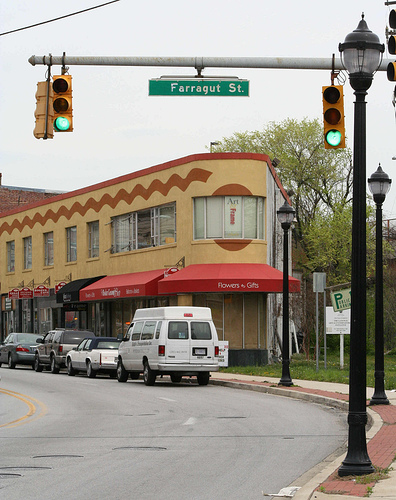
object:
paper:
[262, 485, 299, 498]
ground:
[225, 364, 395, 497]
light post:
[338, 10, 389, 475]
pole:
[338, 95, 372, 474]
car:
[31, 327, 64, 372]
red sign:
[31, 284, 50, 299]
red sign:
[51, 278, 66, 293]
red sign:
[18, 288, 33, 297]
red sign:
[7, 287, 21, 297]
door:
[38, 302, 51, 336]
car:
[0, 332, 43, 369]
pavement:
[0, 361, 349, 499]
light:
[48, 74, 73, 132]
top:
[72, 335, 126, 348]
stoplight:
[322, 70, 346, 152]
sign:
[146, 76, 252, 100]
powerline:
[2, 0, 122, 42]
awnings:
[77, 277, 298, 301]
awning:
[159, 262, 301, 295]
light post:
[273, 192, 297, 385]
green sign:
[329, 282, 351, 311]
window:
[192, 196, 222, 242]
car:
[114, 303, 219, 385]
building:
[0, 120, 299, 399]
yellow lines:
[0, 377, 51, 432]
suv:
[29, 326, 95, 375]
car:
[61, 335, 124, 379]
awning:
[49, 272, 103, 304]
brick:
[378, 453, 389, 460]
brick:
[336, 480, 348, 481]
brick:
[322, 479, 331, 485]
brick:
[368, 452, 375, 468]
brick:
[349, 489, 359, 495]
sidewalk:
[180, 371, 394, 498]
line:
[184, 414, 202, 427]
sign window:
[193, 197, 266, 241]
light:
[334, 47, 384, 74]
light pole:
[336, 7, 385, 477]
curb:
[139, 358, 394, 496]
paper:
[266, 483, 299, 496]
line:
[10, 376, 46, 440]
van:
[131, 304, 223, 386]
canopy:
[56, 277, 87, 305]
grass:
[347, 467, 386, 490]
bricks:
[327, 476, 362, 495]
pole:
[27, 51, 395, 71]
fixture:
[367, 160, 393, 197]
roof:
[70, 331, 119, 350]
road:
[3, 342, 366, 496]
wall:
[217, 336, 274, 373]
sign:
[154, 246, 302, 294]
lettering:
[325, 307, 348, 333]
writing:
[323, 295, 353, 343]